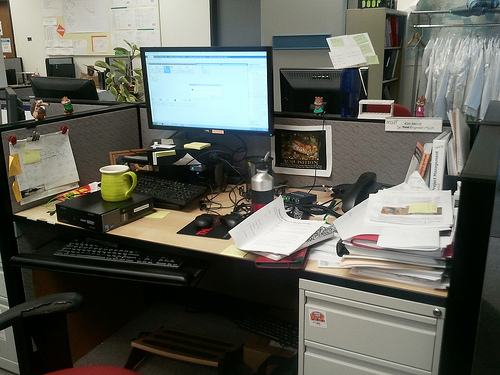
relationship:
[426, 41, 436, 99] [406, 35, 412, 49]
top on clothes hanger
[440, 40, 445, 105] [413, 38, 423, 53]
top on clothes hanger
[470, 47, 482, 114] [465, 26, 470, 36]
top on clothes hanger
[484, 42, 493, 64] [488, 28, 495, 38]
top on clothes hanger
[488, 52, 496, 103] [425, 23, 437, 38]
top on clothes hanger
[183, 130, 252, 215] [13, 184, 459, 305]
wires for electronics on desk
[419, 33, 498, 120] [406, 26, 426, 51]
smocks hanging on hangers